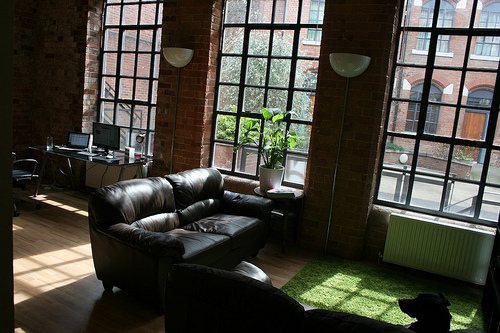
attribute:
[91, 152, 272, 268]
couch — black, leather, empty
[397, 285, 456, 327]
dog — black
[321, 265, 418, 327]
carpet — green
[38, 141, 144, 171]
desk — organized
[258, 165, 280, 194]
pot — white